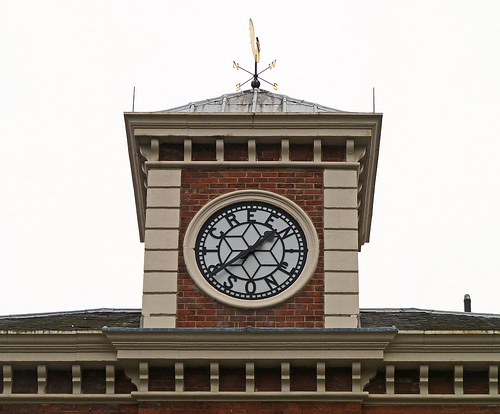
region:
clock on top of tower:
[189, 177, 317, 315]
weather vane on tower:
[218, 2, 295, 93]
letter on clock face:
[243, 205, 258, 222]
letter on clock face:
[278, 225, 298, 242]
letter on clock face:
[283, 246, 299, 257]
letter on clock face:
[262, 272, 278, 289]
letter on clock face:
[243, 279, 260, 294]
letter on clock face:
[223, 274, 235, 289]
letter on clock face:
[201, 243, 220, 258]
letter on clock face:
[203, 225, 225, 242]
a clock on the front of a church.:
[181, 185, 320, 307]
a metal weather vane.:
[228, 18, 278, 89]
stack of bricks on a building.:
[321, 159, 358, 333]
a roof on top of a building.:
[0, 314, 498, 327]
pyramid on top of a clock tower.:
[124, 87, 384, 115]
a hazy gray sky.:
[1, 0, 496, 311]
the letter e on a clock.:
[246, 203, 261, 233]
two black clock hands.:
[210, 225, 283, 277]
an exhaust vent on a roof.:
[449, 291, 481, 318]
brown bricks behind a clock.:
[175, 164, 321, 327]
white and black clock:
[175, 181, 345, 311]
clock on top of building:
[127, 76, 414, 326]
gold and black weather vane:
[205, 18, 302, 94]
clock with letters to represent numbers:
[182, 176, 337, 310]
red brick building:
[127, 139, 371, 342]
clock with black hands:
[192, 166, 385, 308]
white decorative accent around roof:
[27, 337, 472, 401]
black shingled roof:
[42, 288, 114, 330]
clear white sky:
[45, 117, 76, 274]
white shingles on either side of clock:
[136, 156, 383, 326]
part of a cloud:
[438, 151, 460, 180]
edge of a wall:
[348, 248, 358, 281]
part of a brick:
[186, 291, 206, 316]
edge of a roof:
[213, 105, 218, 119]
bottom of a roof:
[173, 375, 192, 377]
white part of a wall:
[339, 250, 345, 282]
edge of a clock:
[349, 242, 360, 280]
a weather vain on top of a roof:
[229, 18, 283, 92]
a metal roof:
[145, 80, 356, 126]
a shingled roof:
[365, 298, 498, 336]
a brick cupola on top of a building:
[118, 114, 366, 346]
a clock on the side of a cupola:
[184, 190, 322, 310]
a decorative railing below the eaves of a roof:
[4, 338, 497, 404]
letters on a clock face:
[185, 194, 325, 298]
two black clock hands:
[213, 226, 278, 278]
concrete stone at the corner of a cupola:
[317, 164, 373, 340]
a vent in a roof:
[458, 291, 481, 319]